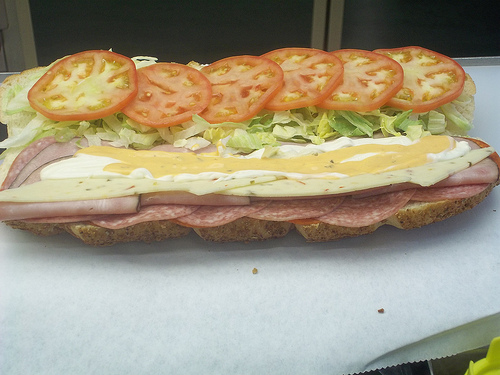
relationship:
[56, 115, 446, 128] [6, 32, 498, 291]
lettuce on top of a sandwich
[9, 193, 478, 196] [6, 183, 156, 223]
ham in pieces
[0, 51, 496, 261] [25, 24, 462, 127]
sub has tomatoes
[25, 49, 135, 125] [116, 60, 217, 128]
tomatoes next to tomato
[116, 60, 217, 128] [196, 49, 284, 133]
tomato next to tomato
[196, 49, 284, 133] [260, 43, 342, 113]
tomato next to tomato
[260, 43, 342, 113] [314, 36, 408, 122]
tomato next to tomato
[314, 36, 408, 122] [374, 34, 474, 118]
tomato next to tomato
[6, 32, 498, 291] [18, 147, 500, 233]
sandwich has meat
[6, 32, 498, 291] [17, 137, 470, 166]
sandwich has sauce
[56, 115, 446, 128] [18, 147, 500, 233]
lettuce underneath meat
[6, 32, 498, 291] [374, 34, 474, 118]
sandwich has tomato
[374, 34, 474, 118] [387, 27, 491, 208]
tomato sitting on end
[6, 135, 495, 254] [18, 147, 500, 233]
bread underneath meat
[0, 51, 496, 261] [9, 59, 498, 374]
sub on top of paper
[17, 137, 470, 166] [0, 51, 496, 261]
sauce on top of sub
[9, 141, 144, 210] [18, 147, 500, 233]
piece of meat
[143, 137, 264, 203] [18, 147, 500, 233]
piece of meat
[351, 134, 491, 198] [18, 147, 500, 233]
piece of meat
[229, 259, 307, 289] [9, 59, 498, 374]
crum on top of paper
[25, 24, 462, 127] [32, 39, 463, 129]
tomatoes are in row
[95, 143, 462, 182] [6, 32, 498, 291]
mustard on top of sandwich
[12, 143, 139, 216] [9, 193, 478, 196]
slice of ham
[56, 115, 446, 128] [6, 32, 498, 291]
lettuce on top of sandwich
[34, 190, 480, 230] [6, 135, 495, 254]
salami on top of bread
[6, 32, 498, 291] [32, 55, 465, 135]
sandwich has veggies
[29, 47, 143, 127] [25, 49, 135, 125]
slice of tomatoes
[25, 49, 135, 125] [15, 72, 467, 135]
tomatoes on top of salad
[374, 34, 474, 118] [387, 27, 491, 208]
tomato on end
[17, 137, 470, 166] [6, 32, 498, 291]
sauce on top of sandwich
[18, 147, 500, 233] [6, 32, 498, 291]
meat on top of sandwich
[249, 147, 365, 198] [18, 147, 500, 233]
piece of meat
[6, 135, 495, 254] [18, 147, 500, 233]
bread under meat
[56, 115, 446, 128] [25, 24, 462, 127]
lettuce under tomatoes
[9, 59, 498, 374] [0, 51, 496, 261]
paper under sub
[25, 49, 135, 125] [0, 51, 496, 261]
tomatoes on sub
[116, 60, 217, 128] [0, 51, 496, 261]
tomato on sub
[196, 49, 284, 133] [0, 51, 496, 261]
tomato on sub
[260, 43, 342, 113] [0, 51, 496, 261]
tomato on sub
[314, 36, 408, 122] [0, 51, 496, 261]
tomato on sub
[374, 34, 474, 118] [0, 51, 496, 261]
tomato on sub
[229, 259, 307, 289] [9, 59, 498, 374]
crum sitting on paper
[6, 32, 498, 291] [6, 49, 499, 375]
sandwich on top of table